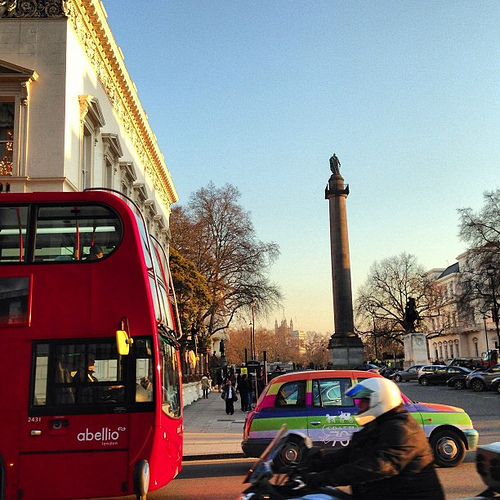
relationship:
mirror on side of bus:
[116, 328, 131, 354] [0, 187, 182, 498]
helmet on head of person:
[345, 376, 400, 429] [305, 375, 446, 498]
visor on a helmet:
[348, 385, 370, 412] [345, 376, 400, 429]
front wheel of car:
[432, 427, 466, 467] [241, 369, 476, 471]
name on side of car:
[321, 409, 357, 442] [241, 369, 476, 471]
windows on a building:
[79, 96, 170, 272] [2, 0, 177, 405]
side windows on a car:
[276, 377, 368, 408] [241, 369, 476, 471]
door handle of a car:
[312, 420, 322, 428] [241, 369, 476, 471]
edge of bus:
[130, 197, 169, 497] [0, 187, 182, 498]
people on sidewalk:
[217, 364, 259, 414] [183, 379, 248, 437]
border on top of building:
[64, 0, 205, 214] [2, 0, 177, 405]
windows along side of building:
[79, 96, 170, 272] [2, 0, 177, 405]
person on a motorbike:
[305, 375, 446, 498] [237, 422, 349, 498]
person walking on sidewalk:
[305, 375, 446, 498] [183, 379, 248, 437]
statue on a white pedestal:
[398, 297, 420, 333] [401, 333, 434, 372]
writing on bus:
[77, 426, 128, 447] [0, 187, 182, 498]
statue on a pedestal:
[398, 297, 420, 333] [401, 333, 434, 372]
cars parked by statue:
[388, 363, 498, 396] [398, 297, 420, 333]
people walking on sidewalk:
[217, 364, 259, 414] [183, 379, 248, 437]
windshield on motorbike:
[244, 425, 288, 486] [237, 422, 349, 498]